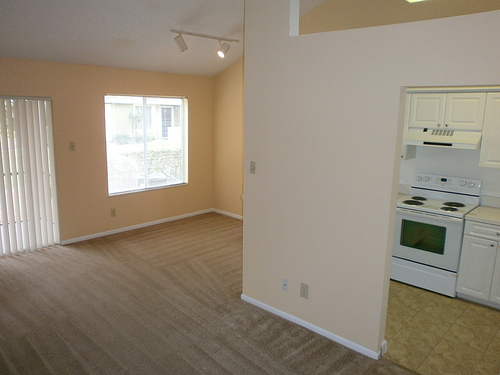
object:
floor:
[2, 212, 378, 374]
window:
[100, 93, 189, 199]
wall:
[53, 65, 247, 242]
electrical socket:
[299, 281, 309, 300]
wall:
[240, 28, 400, 358]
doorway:
[379, 84, 497, 374]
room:
[2, 2, 498, 375]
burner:
[440, 206, 459, 212]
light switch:
[250, 160, 256, 175]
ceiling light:
[217, 43, 232, 58]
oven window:
[397, 219, 446, 255]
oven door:
[392, 210, 463, 273]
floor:
[382, 282, 500, 375]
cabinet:
[402, 90, 487, 140]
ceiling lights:
[173, 35, 189, 53]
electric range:
[466, 182, 475, 189]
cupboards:
[455, 204, 499, 309]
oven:
[389, 172, 481, 298]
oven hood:
[388, 256, 455, 299]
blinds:
[0, 96, 59, 254]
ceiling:
[0, 0, 264, 76]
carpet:
[2, 213, 375, 375]